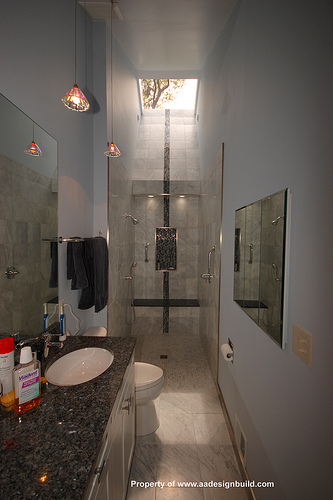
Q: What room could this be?
A: It is a bathroom.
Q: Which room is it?
A: It is a bathroom.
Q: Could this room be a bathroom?
A: Yes, it is a bathroom.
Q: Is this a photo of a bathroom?
A: Yes, it is showing a bathroom.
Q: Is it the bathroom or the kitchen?
A: It is the bathroom.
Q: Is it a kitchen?
A: No, it is a bathroom.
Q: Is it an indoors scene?
A: Yes, it is indoors.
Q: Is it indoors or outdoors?
A: It is indoors.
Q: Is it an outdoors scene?
A: No, it is indoors.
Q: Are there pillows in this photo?
A: No, there are no pillows.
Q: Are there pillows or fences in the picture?
A: No, there are no pillows or fences.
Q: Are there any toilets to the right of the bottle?
A: Yes, there is a toilet to the right of the bottle.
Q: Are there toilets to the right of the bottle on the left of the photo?
A: Yes, there is a toilet to the right of the bottle.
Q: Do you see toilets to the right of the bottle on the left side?
A: Yes, there is a toilet to the right of the bottle.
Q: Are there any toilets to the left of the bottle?
A: No, the toilet is to the right of the bottle.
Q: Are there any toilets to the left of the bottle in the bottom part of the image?
A: No, the toilet is to the right of the bottle.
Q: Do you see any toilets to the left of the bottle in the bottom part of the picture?
A: No, the toilet is to the right of the bottle.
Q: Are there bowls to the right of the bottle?
A: No, there is a toilet to the right of the bottle.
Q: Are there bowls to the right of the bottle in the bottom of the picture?
A: No, there is a toilet to the right of the bottle.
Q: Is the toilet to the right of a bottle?
A: Yes, the toilet is to the right of a bottle.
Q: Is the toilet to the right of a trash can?
A: No, the toilet is to the right of a bottle.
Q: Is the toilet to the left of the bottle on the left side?
A: No, the toilet is to the right of the bottle.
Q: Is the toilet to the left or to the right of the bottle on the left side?
A: The toilet is to the right of the bottle.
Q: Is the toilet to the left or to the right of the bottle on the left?
A: The toilet is to the right of the bottle.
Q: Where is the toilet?
A: The toilet is in the bathroom.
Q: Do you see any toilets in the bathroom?
A: Yes, there is a toilet in the bathroom.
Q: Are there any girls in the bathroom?
A: No, there is a toilet in the bathroom.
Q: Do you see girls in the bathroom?
A: No, there is a toilet in the bathroom.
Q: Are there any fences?
A: No, there are no fences.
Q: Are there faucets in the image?
A: No, there are no faucets.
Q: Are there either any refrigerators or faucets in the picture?
A: No, there are no faucets or refrigerators.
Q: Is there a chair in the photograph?
A: No, there are no chairs.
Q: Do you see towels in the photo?
A: Yes, there is a towel.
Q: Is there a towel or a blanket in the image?
A: Yes, there is a towel.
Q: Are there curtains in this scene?
A: No, there are no curtains.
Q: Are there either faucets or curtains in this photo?
A: No, there are no curtains or faucets.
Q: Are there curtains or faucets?
A: No, there are no curtains or faucets.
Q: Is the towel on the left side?
A: Yes, the towel is on the left of the image.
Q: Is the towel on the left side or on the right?
A: The towel is on the left of the image.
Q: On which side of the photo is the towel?
A: The towel is on the left of the image.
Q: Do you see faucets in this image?
A: No, there are no faucets.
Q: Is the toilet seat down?
A: Yes, the toilet seat is down.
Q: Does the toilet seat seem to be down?
A: Yes, the toilet seat is down.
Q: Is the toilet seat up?
A: No, the toilet seat is down.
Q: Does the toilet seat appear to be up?
A: No, the toilet seat is down.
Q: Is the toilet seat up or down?
A: The toilet seat is down.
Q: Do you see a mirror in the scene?
A: Yes, there is a mirror.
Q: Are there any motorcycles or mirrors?
A: Yes, there is a mirror.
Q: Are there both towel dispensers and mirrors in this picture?
A: No, there is a mirror but no towel dispensers.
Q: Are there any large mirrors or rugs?
A: Yes, there is a large mirror.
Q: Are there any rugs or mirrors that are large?
A: Yes, the mirror is large.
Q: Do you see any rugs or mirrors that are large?
A: Yes, the mirror is large.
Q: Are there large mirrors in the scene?
A: Yes, there is a large mirror.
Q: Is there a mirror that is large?
A: Yes, there is a large mirror.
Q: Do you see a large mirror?
A: Yes, there is a large mirror.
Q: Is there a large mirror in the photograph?
A: Yes, there is a large mirror.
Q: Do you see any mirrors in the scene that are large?
A: Yes, there is a mirror that is large.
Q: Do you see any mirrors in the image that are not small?
A: Yes, there is a large mirror.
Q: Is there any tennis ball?
A: No, there are no tennis balls.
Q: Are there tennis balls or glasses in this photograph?
A: No, there are no tennis balls or glasses.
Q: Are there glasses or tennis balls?
A: No, there are no tennis balls or glasses.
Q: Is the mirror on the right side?
A: Yes, the mirror is on the right of the image.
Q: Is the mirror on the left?
A: No, the mirror is on the right of the image.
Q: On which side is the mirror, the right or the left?
A: The mirror is on the right of the image.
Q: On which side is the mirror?
A: The mirror is on the right of the image.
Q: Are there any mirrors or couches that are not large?
A: No, there is a mirror but it is large.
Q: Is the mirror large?
A: Yes, the mirror is large.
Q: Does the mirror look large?
A: Yes, the mirror is large.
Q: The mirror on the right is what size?
A: The mirror is large.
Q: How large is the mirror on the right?
A: The mirror is large.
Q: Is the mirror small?
A: No, the mirror is large.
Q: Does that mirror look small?
A: No, the mirror is large.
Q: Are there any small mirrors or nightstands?
A: No, there is a mirror but it is large.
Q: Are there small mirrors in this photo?
A: No, there is a mirror but it is large.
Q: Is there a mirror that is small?
A: No, there is a mirror but it is large.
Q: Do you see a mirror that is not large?
A: No, there is a mirror but it is large.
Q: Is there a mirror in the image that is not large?
A: No, there is a mirror but it is large.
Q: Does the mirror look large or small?
A: The mirror is large.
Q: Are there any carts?
A: No, there are no carts.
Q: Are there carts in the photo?
A: No, there are no carts.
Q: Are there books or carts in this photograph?
A: No, there are no carts or books.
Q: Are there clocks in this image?
A: No, there are no clocks.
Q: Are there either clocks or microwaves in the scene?
A: No, there are no clocks or microwaves.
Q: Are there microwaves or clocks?
A: No, there are no clocks or microwaves.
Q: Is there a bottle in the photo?
A: Yes, there is a bottle.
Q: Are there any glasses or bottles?
A: Yes, there is a bottle.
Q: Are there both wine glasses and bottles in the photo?
A: No, there is a bottle but no wine glasses.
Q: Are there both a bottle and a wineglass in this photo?
A: No, there is a bottle but no wine glasses.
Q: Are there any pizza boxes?
A: No, there are no pizza boxes.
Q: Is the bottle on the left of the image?
A: Yes, the bottle is on the left of the image.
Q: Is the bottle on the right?
A: No, the bottle is on the left of the image.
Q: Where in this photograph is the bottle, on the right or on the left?
A: The bottle is on the left of the image.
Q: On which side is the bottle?
A: The bottle is on the left of the image.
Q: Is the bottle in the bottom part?
A: Yes, the bottle is in the bottom of the image.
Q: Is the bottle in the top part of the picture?
A: No, the bottle is in the bottom of the image.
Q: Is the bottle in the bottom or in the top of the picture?
A: The bottle is in the bottom of the image.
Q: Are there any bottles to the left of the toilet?
A: Yes, there is a bottle to the left of the toilet.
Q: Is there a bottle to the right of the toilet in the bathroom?
A: No, the bottle is to the left of the toilet.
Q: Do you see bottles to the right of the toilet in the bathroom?
A: No, the bottle is to the left of the toilet.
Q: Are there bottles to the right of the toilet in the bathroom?
A: No, the bottle is to the left of the toilet.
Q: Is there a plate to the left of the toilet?
A: No, there is a bottle to the left of the toilet.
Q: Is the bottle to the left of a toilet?
A: Yes, the bottle is to the left of a toilet.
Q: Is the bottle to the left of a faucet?
A: No, the bottle is to the left of a toilet.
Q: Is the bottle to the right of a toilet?
A: No, the bottle is to the left of a toilet.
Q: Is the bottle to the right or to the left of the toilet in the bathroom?
A: The bottle is to the left of the toilet.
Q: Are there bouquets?
A: No, there are no bouquets.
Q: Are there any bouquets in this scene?
A: No, there are no bouquets.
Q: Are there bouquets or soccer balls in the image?
A: No, there are no bouquets or soccer balls.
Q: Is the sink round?
A: Yes, the sink is round.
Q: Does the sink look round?
A: Yes, the sink is round.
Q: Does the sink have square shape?
A: No, the sink is round.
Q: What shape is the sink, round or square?
A: The sink is round.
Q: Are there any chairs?
A: No, there are no chairs.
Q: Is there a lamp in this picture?
A: Yes, there is a lamp.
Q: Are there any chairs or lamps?
A: Yes, there is a lamp.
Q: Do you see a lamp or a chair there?
A: Yes, there is a lamp.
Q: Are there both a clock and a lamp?
A: No, there is a lamp but no clocks.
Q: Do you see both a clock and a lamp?
A: No, there is a lamp but no clocks.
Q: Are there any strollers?
A: No, there are no strollers.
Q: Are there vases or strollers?
A: No, there are no strollers or vases.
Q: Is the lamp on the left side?
A: Yes, the lamp is on the left of the image.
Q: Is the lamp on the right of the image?
A: No, the lamp is on the left of the image.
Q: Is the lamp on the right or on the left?
A: The lamp is on the left of the image.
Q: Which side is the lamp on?
A: The lamp is on the left of the image.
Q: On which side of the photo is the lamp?
A: The lamp is on the left of the image.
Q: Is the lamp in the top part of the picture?
A: Yes, the lamp is in the top of the image.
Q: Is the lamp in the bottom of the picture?
A: No, the lamp is in the top of the image.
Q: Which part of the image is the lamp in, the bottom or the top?
A: The lamp is in the top of the image.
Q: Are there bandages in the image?
A: No, there are no bandages.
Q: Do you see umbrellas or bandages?
A: No, there are no bandages or umbrellas.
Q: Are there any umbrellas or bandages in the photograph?
A: No, there are no bandages or umbrellas.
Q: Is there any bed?
A: No, there are no beds.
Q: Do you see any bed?
A: No, there are no beds.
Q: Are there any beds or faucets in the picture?
A: No, there are no beds or faucets.